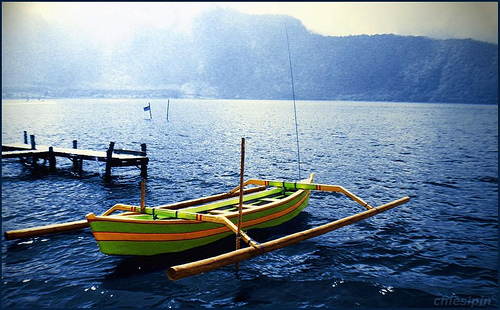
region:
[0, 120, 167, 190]
a boat dock in the water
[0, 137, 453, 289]
a yellow fishing boat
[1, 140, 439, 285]
a boat in the water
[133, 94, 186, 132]
a flag in the water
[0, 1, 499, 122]
mountains in the background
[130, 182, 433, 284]
a balance poll for the boat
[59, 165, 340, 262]
an orange stripe on a boat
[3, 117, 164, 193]
an empty dock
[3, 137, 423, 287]
an empty anchored boat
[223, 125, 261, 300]
an anchor poll in the water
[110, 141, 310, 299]
green boat on sea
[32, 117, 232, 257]
green boat on sea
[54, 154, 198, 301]
green boat on sea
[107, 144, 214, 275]
green boat on sea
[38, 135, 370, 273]
green wooden canoe in river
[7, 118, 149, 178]
wooden dock on river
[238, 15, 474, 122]
grassy hills in distance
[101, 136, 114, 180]
wood post on dock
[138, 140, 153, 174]
wood post on dock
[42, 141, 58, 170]
wood post on dock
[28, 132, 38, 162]
wood post on dock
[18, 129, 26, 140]
wood post on dock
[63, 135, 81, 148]
wood post on dock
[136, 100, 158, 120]
flag on post in lake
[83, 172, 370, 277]
boat in the water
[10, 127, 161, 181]
dock in the water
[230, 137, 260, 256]
pole next to the boat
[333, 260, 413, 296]
waves in the water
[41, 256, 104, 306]
waves in the water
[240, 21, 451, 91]
mountain across the lake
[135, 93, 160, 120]
bouy in the water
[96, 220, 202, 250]
stripe on the side of the boat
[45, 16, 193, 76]
fog in the mountains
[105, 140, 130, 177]
post on the side of the dock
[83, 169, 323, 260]
a green boat on the water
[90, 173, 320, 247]
an orange stripe on the boat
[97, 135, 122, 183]
a wooden post on the water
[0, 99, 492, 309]
a large lake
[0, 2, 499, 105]
mountains behind the lake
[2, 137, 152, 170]
an old wooden dock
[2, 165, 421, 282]
wooden boards on the boat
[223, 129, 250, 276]
a wooden pole next to the boat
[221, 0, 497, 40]
a gray sky overhead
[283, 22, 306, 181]
a black wire